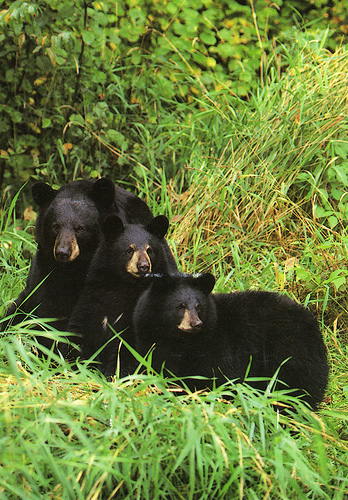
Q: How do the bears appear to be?
A: Alert.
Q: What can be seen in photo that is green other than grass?
A: Leaves.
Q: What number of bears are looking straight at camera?
A: One.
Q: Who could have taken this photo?
A: Wildlife photographer.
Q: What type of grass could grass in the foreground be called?
A: Monkey grass.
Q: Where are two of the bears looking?
A: To their left.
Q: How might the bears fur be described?
A: Short.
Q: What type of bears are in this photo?
A: Black bears.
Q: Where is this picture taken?
A: In front of the woods.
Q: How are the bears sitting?
A: Smallest to largest in ascending order.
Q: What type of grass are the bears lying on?
A: Wheat grass.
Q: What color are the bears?
A: Black.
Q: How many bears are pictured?
A: 3.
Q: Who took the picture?
A: The photographer.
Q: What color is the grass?
A: Green.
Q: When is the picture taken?
A: Daytime.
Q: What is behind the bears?
A: Grass.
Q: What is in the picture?
A: Bears.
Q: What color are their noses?
A: Black.